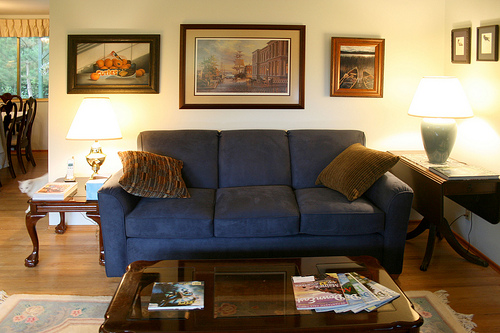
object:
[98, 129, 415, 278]
couch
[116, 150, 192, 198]
pillow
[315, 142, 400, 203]
pillow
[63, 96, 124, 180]
table lamp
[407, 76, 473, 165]
table lamp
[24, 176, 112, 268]
end table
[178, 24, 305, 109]
art print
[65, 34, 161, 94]
art print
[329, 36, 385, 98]
art print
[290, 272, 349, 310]
magazine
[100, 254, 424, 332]
center table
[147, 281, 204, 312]
magazine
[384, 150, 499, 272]
side table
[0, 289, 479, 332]
rug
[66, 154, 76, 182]
bottle of water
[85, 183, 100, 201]
box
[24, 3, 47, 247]
wall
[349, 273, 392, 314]
magazine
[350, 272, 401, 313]
magazine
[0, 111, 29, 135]
table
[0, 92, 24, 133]
chair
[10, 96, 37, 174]
chair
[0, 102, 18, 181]
chair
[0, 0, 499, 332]
living room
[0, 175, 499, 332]
floor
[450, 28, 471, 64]
frame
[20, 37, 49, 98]
tree